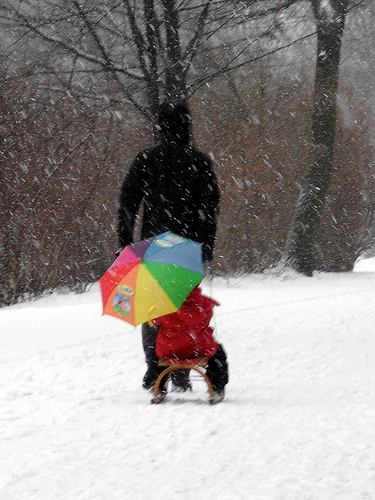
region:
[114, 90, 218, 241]
this is a man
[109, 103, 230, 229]
he is wearing a jacket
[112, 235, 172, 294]
the umbrella is colorful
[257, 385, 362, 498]
the snow is all over the place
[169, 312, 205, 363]
the jacket is red in color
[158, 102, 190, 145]
this is a hood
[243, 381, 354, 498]
the snow is white in color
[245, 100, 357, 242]
the weather is snow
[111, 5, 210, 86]
the tree is woody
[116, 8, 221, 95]
the tree is dry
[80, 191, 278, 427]
child on a sled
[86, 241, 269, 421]
the jacket is red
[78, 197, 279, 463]
the sled is wooden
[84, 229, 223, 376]
the umbrella is rainbow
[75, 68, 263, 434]
adult pulls the child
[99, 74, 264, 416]
adult is wearing black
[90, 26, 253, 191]
the snow is falling hard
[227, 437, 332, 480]
this snow is white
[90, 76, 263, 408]
parent and child in the snow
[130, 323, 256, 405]
the child's pants are black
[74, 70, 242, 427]
A man and a child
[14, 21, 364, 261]
Heavy snow fall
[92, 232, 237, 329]
Rainbow umbrella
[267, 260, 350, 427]
White snow on the ground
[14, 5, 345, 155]
Leafless trees on the hilly area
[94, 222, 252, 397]
A child holding a rainbow umbrella in snowfall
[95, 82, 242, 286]
A man in black jacket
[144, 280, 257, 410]
A child wearing red jacket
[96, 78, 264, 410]
A child with a parent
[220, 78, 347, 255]
Brown vegetation in cold weather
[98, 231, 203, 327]
The colorful umbrella.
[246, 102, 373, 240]
The snow is falling.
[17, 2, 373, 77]
The trees have no leaves.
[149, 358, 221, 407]
The sled is a bench.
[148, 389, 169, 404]
One of the skiis.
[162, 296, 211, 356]
A childs red jacket.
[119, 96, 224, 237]
Man covered in black.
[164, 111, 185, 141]
Guy wearing a mask.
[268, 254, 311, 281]
Snow piles on the trunck.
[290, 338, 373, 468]
The snow is pure white.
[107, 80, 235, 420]
person in black jacket walking in snow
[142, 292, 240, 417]
child in red jacket on rounded sleigh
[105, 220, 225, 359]
child with rainbow colored umbrella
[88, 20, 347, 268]
two large bare trees in photograph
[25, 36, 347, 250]
snowing in photograph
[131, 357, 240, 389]
child wearing black pants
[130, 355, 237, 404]
sleigh is brown and rounded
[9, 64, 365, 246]
row of bare bushes near two tress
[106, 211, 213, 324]
umbrella has two advertisements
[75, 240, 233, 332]
advertisements on orange and blue sections of umbrealla